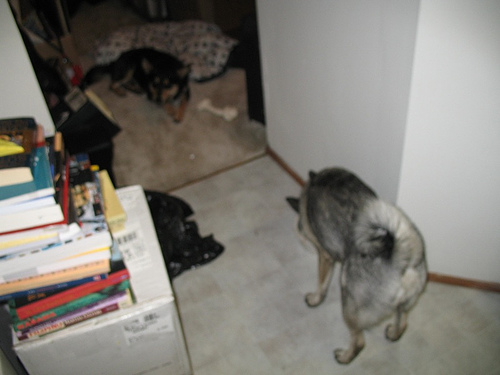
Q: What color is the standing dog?
A: Grey.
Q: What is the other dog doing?
A: Laying down.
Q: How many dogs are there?
A: Two.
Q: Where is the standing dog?
A: By the wall.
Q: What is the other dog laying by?
A: A bed.